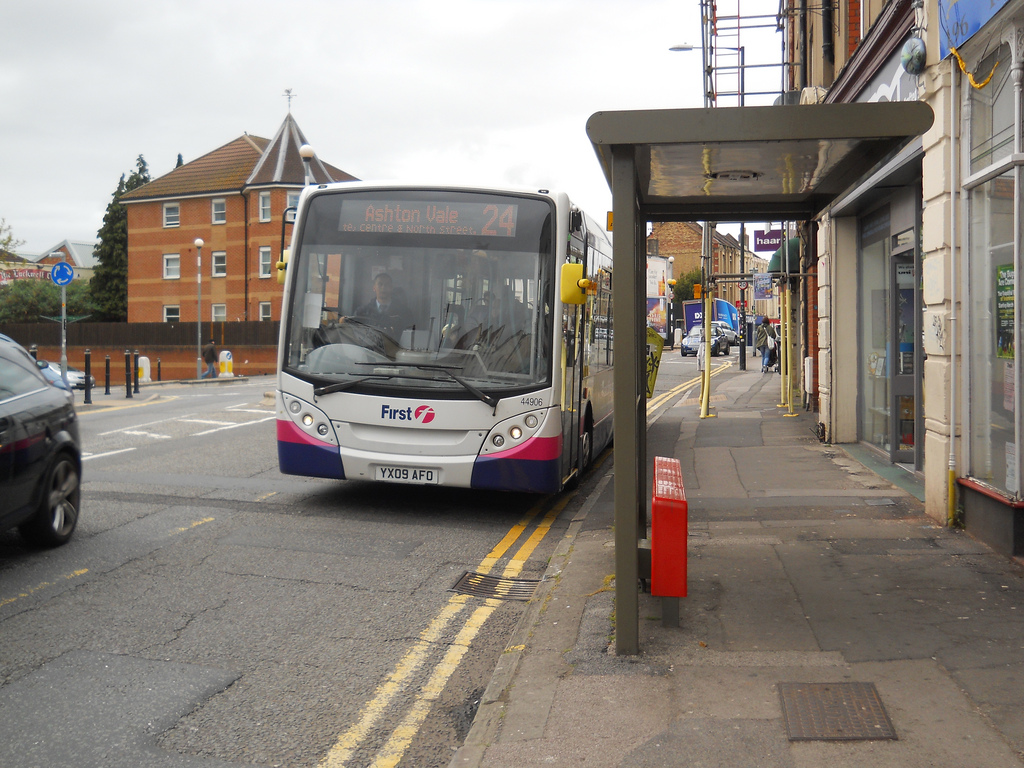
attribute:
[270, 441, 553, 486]
purple stripe — pink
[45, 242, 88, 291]
sign — circular, blue, yellow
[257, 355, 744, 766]
yellow lines — double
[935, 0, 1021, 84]
blue sign — above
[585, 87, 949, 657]
bust stop — bus, covered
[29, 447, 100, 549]
tire — real